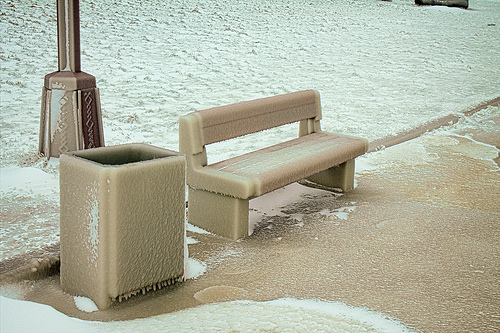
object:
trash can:
[59, 143, 186, 306]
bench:
[178, 89, 369, 240]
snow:
[0, 294, 104, 332]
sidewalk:
[0, 104, 499, 332]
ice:
[111, 296, 499, 332]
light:
[38, 1, 105, 160]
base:
[38, 71, 105, 160]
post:
[56, 1, 81, 70]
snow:
[97, 0, 410, 88]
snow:
[240, 179, 345, 235]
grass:
[0, 0, 55, 48]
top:
[179, 88, 321, 155]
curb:
[0, 95, 499, 284]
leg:
[186, 186, 249, 240]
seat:
[186, 130, 368, 199]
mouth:
[76, 144, 174, 165]